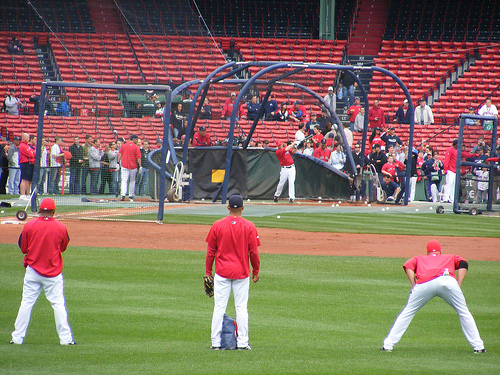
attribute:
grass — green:
[259, 254, 367, 366]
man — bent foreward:
[391, 234, 489, 352]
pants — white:
[387, 273, 488, 348]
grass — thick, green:
[285, 303, 327, 342]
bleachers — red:
[2, 31, 498, 168]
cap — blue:
[201, 177, 281, 222]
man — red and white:
[367, 217, 476, 357]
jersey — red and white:
[16, 219, 66, 279]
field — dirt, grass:
[0, 196, 498, 373]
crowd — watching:
[4, 129, 146, 204]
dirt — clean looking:
[321, 235, 368, 261]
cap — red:
[36, 196, 58, 213]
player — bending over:
[329, 225, 480, 373]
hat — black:
[228, 192, 242, 207]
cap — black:
[228, 193, 244, 209]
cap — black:
[128, 132, 138, 139]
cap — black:
[198, 122, 208, 130]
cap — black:
[319, 136, 326, 143]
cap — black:
[326, 130, 333, 140]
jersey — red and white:
[271, 143, 301, 167]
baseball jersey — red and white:
[203, 215, 265, 279]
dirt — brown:
[4, 212, 496, 264]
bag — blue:
[218, 311, 239, 351]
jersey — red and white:
[384, 250, 484, 351]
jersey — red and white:
[206, 213, 260, 345]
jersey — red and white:
[11, 214, 71, 345]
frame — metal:
[173, 56, 414, 206]